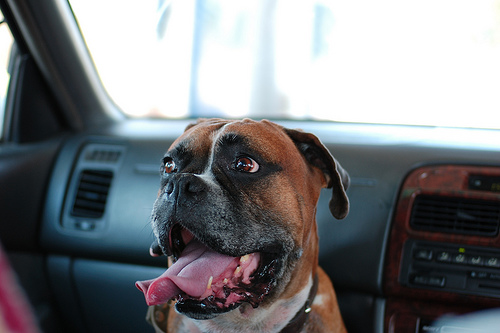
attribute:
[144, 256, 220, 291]
tongue — red, big, out, curled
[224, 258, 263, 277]
teeth — yellow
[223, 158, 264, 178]
eyes — brown, big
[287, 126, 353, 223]
ear — floppy, floopy, brown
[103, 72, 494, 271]
car — black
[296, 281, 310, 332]
collar — black, brown, leather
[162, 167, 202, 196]
nose — black, wet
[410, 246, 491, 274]
symbols — white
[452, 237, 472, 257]
light — green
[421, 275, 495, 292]
radio — black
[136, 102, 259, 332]
dog — brown, sitting, panting, hot, waiting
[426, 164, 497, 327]
panel — wood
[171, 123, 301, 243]
face — big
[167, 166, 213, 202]
nostril — black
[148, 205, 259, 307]
mouth — open, wide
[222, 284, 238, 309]
gums — pink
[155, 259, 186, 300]
tounge — out